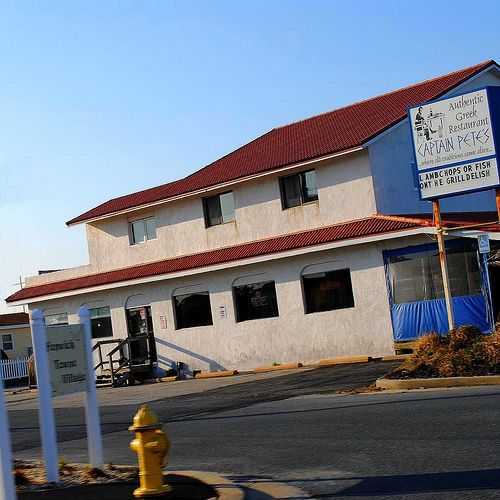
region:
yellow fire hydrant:
[110, 395, 185, 494]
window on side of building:
[291, 256, 366, 323]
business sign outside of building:
[396, 88, 498, 333]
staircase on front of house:
[88, 328, 156, 389]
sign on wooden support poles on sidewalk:
[17, 293, 121, 490]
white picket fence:
[1, 348, 33, 393]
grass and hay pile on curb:
[386, 317, 498, 379]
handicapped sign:
[468, 230, 495, 260]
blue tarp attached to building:
[390, 287, 495, 342]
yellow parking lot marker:
[248, 355, 303, 377]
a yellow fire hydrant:
[108, 397, 195, 499]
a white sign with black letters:
[22, 313, 122, 423]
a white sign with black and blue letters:
[399, 88, 499, 192]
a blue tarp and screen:
[385, 245, 490, 344]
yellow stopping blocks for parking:
[142, 347, 392, 384]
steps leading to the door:
[95, 329, 175, 389]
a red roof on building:
[12, 59, 454, 305]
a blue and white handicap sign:
[464, 224, 490, 264]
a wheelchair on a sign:
[476, 232, 490, 247]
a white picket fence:
[3, 351, 37, 391]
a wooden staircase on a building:
[85, 320, 168, 401]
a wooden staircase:
[72, 328, 178, 409]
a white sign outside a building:
[12, 303, 129, 492]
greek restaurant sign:
[391, 95, 498, 171]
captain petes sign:
[392, 94, 497, 166]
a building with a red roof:
[80, 60, 470, 225]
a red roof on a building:
[134, 85, 452, 211]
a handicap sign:
[451, 220, 496, 265]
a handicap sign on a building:
[463, 224, 499, 271]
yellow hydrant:
[112, 401, 169, 496]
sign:
[382, 79, 494, 189]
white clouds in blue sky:
[67, 35, 102, 61]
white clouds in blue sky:
[170, 48, 220, 93]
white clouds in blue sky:
[72, 131, 90, 149]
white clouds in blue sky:
[251, 36, 295, 61]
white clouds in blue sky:
[305, 9, 350, 47]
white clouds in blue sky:
[91, 72, 125, 87]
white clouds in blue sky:
[85, 58, 150, 102]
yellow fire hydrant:
[127, 403, 175, 499]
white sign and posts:
[30, 304, 102, 484]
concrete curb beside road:
[11, 457, 246, 499]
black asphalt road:
[8, 389, 499, 498]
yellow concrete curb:
[376, 376, 499, 390]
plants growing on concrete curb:
[391, 323, 499, 375]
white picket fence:
[0, 355, 30, 382]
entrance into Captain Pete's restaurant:
[86, 302, 153, 389]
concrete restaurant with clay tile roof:
[4, 60, 497, 382]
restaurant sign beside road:
[405, 85, 497, 330]